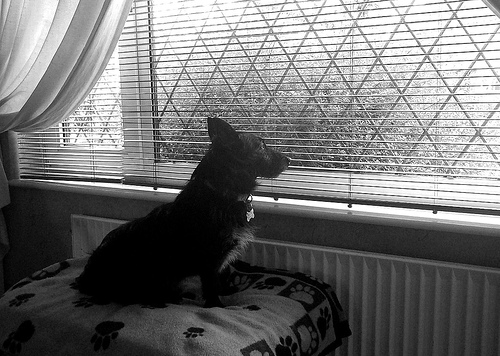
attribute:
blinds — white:
[14, 0, 497, 215]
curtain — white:
[0, 1, 134, 205]